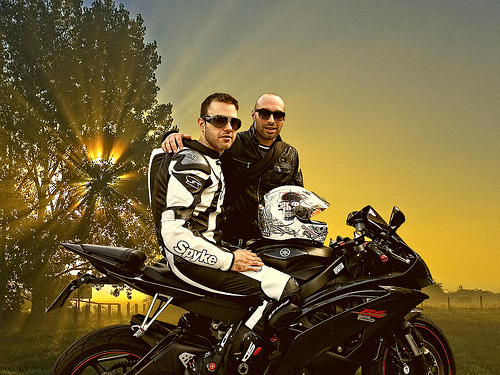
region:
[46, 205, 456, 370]
a black and red motorcycle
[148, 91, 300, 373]
a seated man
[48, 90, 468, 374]
two men posing with motorcycle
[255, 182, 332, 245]
white and black graphic motorcycle helmet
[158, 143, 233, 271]
white and black motorcycle jacket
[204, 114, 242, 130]
black pair of sunglasses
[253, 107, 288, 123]
black pair of sunglasses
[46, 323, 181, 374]
rear black and red motorcycle tire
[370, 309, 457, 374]
black and red front motorcycle tire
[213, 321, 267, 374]
black motorcycle boot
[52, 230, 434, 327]
Black color bike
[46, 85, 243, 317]
A person sitting in the bike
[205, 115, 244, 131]
A person wearing goggles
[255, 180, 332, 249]
Helmet kept in the bike tank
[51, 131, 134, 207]
Sunset behind the tree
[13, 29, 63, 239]
Tree with branches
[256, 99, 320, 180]
A person standing near the bike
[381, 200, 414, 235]
Side mirror of the bike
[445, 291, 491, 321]
Metal rod with fencing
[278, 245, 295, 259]
Logo of the bike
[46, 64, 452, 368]
the two men are posed for the photo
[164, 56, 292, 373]
the one man sits on the motorcycle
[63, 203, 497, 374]
the motorcycle is black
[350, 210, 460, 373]
it has red trim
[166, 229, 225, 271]
The word Spyke appears on his sleeve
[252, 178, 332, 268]
his helmet is white with black figures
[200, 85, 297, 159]
both men are wearing sunglasses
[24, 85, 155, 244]
the sun is radiating thru the trees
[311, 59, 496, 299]
the background is bathed in yellow light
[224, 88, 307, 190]
the man is wearing a black leather jacket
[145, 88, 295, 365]
Man sitting on motorcycle.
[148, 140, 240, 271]
Man dressed in black and white leather jacket.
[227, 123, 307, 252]
Man standing dressed in black leather jacket.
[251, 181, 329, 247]
White helmet with black designs.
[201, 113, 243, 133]
Man wearing sunglasses over eyes.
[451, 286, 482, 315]
Cow standing in pasture in distance.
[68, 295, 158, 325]
Fence surrounding a pasture.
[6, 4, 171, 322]
Tree growing near tree behind men.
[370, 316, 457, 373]
Red circling tire rim.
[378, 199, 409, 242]
Right turn signal light on motorcycle.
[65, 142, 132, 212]
sun shining through the trees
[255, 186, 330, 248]
helmet on the bike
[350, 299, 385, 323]
red logo on the bike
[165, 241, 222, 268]
spyke on the arm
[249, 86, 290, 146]
the head without hair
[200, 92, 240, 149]
the head with hair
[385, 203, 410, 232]
mirror on the bike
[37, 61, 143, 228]
tree with the sun shining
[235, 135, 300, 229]
the black leather jacket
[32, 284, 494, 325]
fence in the background